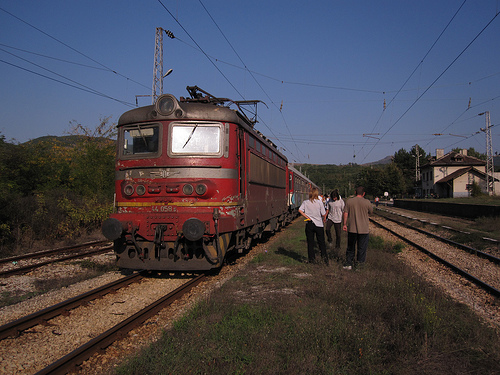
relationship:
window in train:
[118, 124, 158, 159] [86, 62, 389, 328]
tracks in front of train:
[2, 271, 198, 370] [97, 81, 322, 273]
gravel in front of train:
[2, 274, 229, 373] [97, 81, 322, 273]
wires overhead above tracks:
[2, 3, 311, 164] [2, 240, 224, 373]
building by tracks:
[416, 148, 499, 198] [373, 205, 497, 301]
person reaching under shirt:
[298, 186, 333, 266] [298, 194, 325, 225]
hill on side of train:
[2, 131, 111, 253] [97, 81, 322, 273]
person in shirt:
[298, 186, 333, 266] [300, 198, 323, 225]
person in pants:
[298, 186, 333, 266] [305, 219, 326, 261]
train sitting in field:
[97, 81, 322, 273] [2, 199, 484, 373]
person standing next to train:
[298, 186, 333, 266] [97, 81, 322, 273]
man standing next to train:
[341, 184, 376, 269] [97, 81, 322, 273]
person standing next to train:
[320, 192, 330, 215] [97, 81, 322, 273]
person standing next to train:
[323, 189, 345, 249] [97, 81, 322, 273]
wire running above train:
[158, 0, 299, 160] [97, 81, 322, 273]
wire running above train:
[2, 10, 154, 90] [97, 81, 322, 273]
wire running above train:
[173, 37, 399, 95] [97, 81, 322, 273]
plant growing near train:
[52, 194, 85, 241] [97, 81, 322, 273]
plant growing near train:
[26, 198, 74, 248] [97, 81, 322, 273]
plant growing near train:
[76, 193, 105, 229] [97, 81, 322, 273]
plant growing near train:
[1, 194, 38, 223] [97, 81, 322, 273]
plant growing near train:
[2, 226, 24, 257] [97, 81, 322, 273]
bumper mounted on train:
[99, 215, 125, 240] [97, 81, 322, 273]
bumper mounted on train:
[180, 216, 207, 243] [97, 81, 322, 273]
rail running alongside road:
[369, 210, 484, 293] [378, 201, 484, 230]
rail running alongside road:
[372, 210, 482, 262] [378, 201, 484, 230]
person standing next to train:
[321, 193, 329, 207] [97, 81, 322, 273]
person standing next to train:
[338, 193, 346, 210] [97, 81, 322, 273]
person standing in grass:
[298, 186, 333, 266] [120, 213, 490, 372]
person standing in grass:
[323, 189, 345, 249] [120, 213, 490, 372]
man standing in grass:
[341, 184, 376, 269] [120, 213, 490, 372]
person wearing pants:
[298, 186, 333, 266] [302, 216, 331, 263]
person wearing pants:
[323, 189, 345, 249] [323, 215, 343, 248]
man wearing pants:
[341, 184, 376, 269] [342, 230, 368, 264]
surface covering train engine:
[112, 115, 290, 239] [112, 99, 292, 235]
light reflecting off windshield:
[169, 123, 219, 153] [168, 124, 221, 154]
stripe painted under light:
[113, 200, 240, 209] [122, 182, 136, 194]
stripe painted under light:
[113, 200, 240, 209] [134, 182, 145, 194]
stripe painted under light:
[113, 200, 240, 209] [181, 180, 195, 194]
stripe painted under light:
[113, 200, 240, 209] [195, 183, 206, 195]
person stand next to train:
[298, 186, 333, 266] [97, 81, 322, 273]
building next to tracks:
[416, 148, 499, 198] [373, 205, 497, 301]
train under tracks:
[97, 81, 322, 273] [2, 271, 198, 370]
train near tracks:
[97, 81, 322, 273] [373, 205, 497, 301]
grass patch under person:
[115, 216, 497, 369] [298, 186, 333, 266]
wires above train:
[1, 0, 497, 151] [97, 81, 322, 273]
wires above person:
[1, 0, 497, 151] [298, 186, 333, 266]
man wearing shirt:
[341, 184, 376, 269] [340, 195, 375, 231]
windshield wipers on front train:
[134, 122, 199, 147] [97, 81, 322, 273]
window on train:
[168, 122, 229, 160] [121, 108, 291, 254]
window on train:
[118, 124, 158, 159] [121, 108, 291, 254]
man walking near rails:
[341, 184, 376, 269] [40, 231, 226, 371]